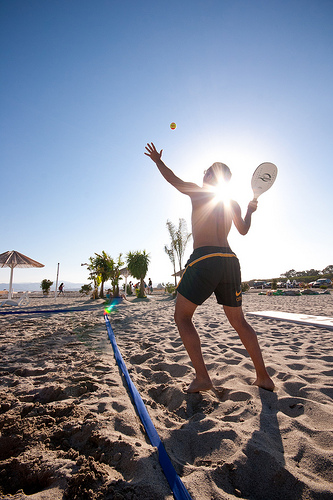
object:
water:
[1, 284, 83, 290]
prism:
[103, 296, 119, 317]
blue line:
[104, 311, 190, 499]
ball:
[170, 121, 177, 130]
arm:
[162, 164, 199, 197]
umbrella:
[116, 267, 134, 297]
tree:
[109, 249, 122, 296]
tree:
[95, 249, 113, 294]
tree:
[83, 255, 100, 299]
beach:
[0, 281, 331, 499]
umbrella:
[0, 250, 43, 308]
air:
[1, 2, 327, 273]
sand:
[1, 290, 332, 499]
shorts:
[174, 246, 243, 307]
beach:
[26, 292, 72, 355]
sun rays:
[180, 160, 245, 227]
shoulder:
[224, 193, 242, 212]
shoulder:
[181, 182, 203, 199]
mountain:
[17, 283, 36, 293]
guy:
[143, 141, 277, 392]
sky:
[0, 0, 332, 287]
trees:
[320, 265, 333, 285]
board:
[249, 301, 332, 330]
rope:
[1, 305, 92, 316]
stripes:
[185, 249, 238, 268]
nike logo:
[236, 289, 242, 302]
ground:
[4, 287, 327, 497]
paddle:
[251, 162, 278, 201]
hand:
[248, 200, 258, 212]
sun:
[202, 167, 251, 213]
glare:
[207, 178, 239, 207]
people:
[57, 282, 65, 295]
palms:
[127, 250, 151, 297]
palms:
[166, 216, 191, 283]